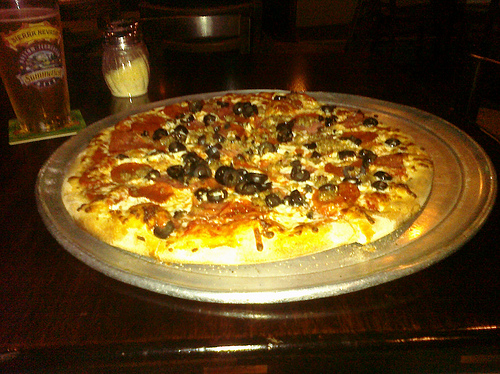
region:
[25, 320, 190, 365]
brown shiny mahogany table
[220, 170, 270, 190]
black pizza toppings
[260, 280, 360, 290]
a big white round plate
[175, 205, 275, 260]
munchy yellow tasty pizza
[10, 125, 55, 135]
green flowered paper mat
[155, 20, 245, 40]
clean metal shiny object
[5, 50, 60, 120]
half filled bottle jar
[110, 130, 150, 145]
red round pizza toppings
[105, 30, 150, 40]
grey shiny bottle top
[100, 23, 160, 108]
Shredded cheese inside of container.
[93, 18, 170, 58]
Silver lid on top of cheese container.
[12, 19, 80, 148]
Sierra nevada beer pint.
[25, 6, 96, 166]
Beer is almost full.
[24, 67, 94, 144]
Beer is sitting on a beverage coaster.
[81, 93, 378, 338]
Pizza is on top of silver tray.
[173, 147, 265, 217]
Black olives on top of pizza.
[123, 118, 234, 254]
Pepperoni is on top of pizza.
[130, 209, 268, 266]
Crust is golden brown.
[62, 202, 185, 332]
Silver tray is sitting brown table.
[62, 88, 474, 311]
The pizza is on a silver circular pan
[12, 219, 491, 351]
A dark wooden tabletop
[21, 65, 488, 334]
The silver pan is on top of the dark wooden table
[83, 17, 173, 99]
Cheese in a clear shaker with a silver top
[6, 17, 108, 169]
The cup is on a green coaster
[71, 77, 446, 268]
The pizza has cheese, olives, pepperoni and sausage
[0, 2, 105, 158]
The clear cup has Sierra Nevada's logo on it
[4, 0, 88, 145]
The clear cup is full of light brown beer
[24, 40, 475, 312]
The pizza is on the left side of the silver pan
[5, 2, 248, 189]
The cup and shaker are to the left of the pizza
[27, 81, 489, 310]
pizza on a pan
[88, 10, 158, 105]
a shaker of cheese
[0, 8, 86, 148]
tall glass of beer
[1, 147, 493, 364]
wooden table under the pizza and beer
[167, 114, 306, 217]
black olives on the pizza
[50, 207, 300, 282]
golden brown pizza crust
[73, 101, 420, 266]
pepperoni, cheese and black olives cover the pizza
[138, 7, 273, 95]
chair at another table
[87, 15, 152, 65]
metal top for a cheese shaker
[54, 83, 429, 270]
a whole pizza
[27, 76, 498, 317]
A METAL PIZZA PLATTER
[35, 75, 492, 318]
A PIZZA ON A PLATTER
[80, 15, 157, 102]
A GRATED CHEESE SHAKER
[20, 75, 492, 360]
A PIZZA PLATTER ON A TABLE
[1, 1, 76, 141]
A GLASS OF BEER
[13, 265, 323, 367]
A DARK WOODEN TABLE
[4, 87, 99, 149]
A COASTER UNDER A GLASS OF BEER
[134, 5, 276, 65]
THE BACK OF A WOODEN CHAIR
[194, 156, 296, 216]
BLACK OLIVES AND CHEESE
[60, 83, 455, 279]
A BLACK OLIVE PEPPERONI PIZZA